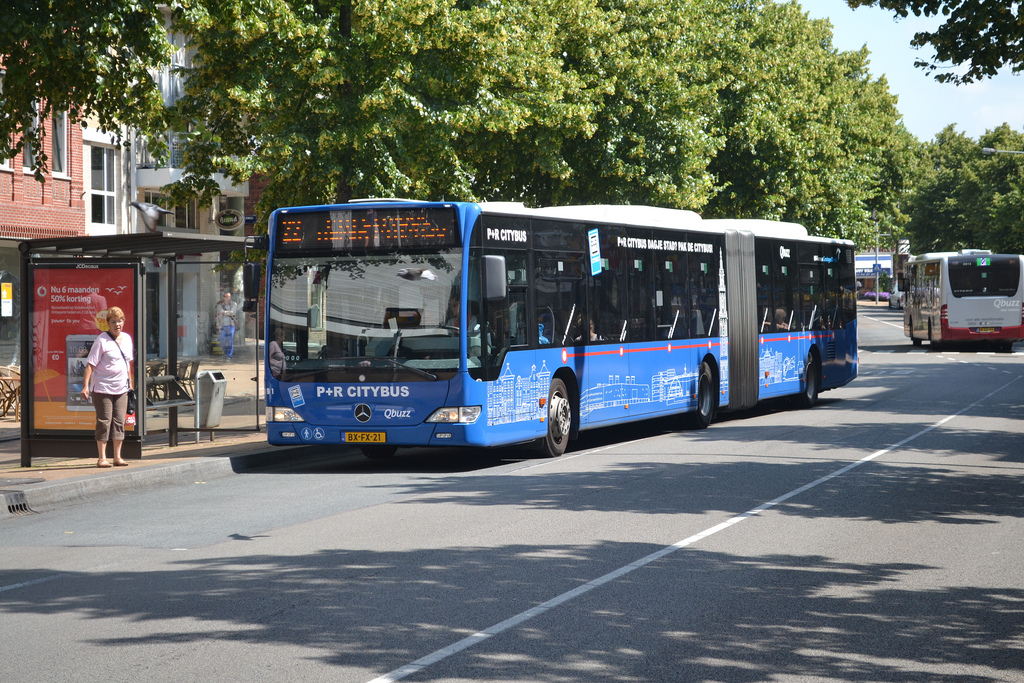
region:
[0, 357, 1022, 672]
The road.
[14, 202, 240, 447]
A bus stop.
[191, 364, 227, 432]
A silver trashcan.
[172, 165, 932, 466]
A blue and white bus.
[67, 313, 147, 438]
A woman wearing a white shirt.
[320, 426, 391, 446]
A yellow and black license plate on the front of a bus.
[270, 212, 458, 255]
A display on the front of a bus.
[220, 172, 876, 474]
blue bus on the road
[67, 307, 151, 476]
woman standing on the side of the road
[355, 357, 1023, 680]
white line on the street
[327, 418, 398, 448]
yellow and black license plate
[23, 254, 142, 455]
ad at the bus stop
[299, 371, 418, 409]
white writing on the front of the bus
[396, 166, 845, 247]
roof of the bus is white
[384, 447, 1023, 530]
shadow o the road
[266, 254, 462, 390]
large windshield on the front of the bus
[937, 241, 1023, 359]
back of a bus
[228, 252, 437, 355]
window on the bus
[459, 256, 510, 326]
window on the bus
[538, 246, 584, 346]
window on the bus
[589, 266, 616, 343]
window on the bus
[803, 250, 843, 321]
window on the bus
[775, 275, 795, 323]
window on the bus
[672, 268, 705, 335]
window on the bus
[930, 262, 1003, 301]
window on the bus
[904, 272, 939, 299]
window on the bus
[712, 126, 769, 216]
green leaves on the tree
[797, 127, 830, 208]
green leaves on the tree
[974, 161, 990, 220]
green leaves on the tree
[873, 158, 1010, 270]
green leaves on the tree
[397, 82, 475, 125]
green leaves on the tree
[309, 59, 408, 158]
green leaves on the tree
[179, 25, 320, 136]
green leaves on the tree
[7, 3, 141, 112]
green leaves on the tree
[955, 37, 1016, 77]
green leaves on the tree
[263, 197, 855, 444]
Blue bus at bus stop on street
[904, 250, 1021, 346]
Red and white bus heading away from camera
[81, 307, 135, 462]
Woman standing at bus stop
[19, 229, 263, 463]
Bus stop covered area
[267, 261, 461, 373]
Front window of blue bus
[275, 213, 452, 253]
Route and bus number sign on blue bus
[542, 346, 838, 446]
Tires on blue bus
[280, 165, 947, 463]
black and blue bus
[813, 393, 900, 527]
white line on road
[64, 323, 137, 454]
woman in bus stop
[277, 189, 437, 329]
orange LCD on bus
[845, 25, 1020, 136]
blue and clear sky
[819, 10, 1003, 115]
no clouds in sky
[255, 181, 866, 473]
blue bus on street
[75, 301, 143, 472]
woman in white t-shirt standing at bus stop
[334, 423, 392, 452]
yellow license plate on front of bus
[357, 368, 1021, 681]
white line on street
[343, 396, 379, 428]
silver emblem on front of bus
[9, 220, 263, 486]
bus stop covered waiting area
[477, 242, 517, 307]
rear view mirror on side of blue and black bus